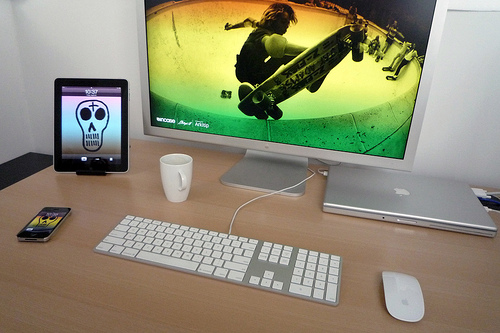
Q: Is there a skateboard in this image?
A: Yes, there is a skateboard.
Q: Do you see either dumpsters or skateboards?
A: Yes, there is a skateboard.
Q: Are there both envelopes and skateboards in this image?
A: No, there is a skateboard but no envelopes.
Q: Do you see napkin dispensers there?
A: No, there are no napkin dispensers.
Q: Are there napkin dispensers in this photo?
A: No, there are no napkin dispensers.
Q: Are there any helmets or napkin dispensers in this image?
A: No, there are no napkin dispensers or helmets.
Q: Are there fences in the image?
A: No, there are no fences.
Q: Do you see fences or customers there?
A: No, there are no fences or customers.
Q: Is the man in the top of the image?
A: Yes, the man is in the top of the image.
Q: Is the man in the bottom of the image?
A: No, the man is in the top of the image.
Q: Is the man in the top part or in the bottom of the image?
A: The man is in the top of the image.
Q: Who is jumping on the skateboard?
A: The man is jumping on the skateboard.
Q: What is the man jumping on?
A: The man is jumping on the skateboard.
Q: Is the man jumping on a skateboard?
A: Yes, the man is jumping on a skateboard.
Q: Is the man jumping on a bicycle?
A: No, the man is jumping on a skateboard.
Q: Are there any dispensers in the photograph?
A: No, there are no dispensers.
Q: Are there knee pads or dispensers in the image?
A: No, there are no dispensers or knee pads.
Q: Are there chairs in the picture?
A: No, there are no chairs.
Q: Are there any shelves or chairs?
A: No, there are no chairs or shelves.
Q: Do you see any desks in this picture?
A: Yes, there is a desk.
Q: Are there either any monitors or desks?
A: Yes, there is a desk.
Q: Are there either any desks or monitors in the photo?
A: Yes, there is a desk.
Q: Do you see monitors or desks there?
A: Yes, there is a desk.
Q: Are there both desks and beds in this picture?
A: No, there is a desk but no beds.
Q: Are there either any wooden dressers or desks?
A: Yes, there is a wood desk.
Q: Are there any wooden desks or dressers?
A: Yes, there is a wood desk.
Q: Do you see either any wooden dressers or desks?
A: Yes, there is a wood desk.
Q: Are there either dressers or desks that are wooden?
A: Yes, the desk is wooden.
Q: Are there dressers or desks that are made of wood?
A: Yes, the desk is made of wood.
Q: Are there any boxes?
A: No, there are no boxes.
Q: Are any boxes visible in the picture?
A: No, there are no boxes.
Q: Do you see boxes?
A: No, there are no boxes.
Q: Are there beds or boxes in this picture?
A: No, there are no boxes or beds.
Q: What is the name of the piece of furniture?
A: The piece of furniture is a desk.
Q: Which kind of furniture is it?
A: The piece of furniture is a desk.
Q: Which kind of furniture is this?
A: This is a desk.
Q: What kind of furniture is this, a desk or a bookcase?
A: This is a desk.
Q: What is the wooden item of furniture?
A: The piece of furniture is a desk.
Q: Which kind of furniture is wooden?
A: The furniture is a desk.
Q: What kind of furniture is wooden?
A: The furniture is a desk.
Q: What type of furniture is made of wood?
A: The furniture is a desk.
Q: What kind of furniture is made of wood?
A: The furniture is a desk.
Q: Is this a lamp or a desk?
A: This is a desk.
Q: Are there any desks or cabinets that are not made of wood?
A: No, there is a desk but it is made of wood.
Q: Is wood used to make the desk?
A: Yes, the desk is made of wood.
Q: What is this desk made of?
A: The desk is made of wood.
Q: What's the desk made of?
A: The desk is made of wood.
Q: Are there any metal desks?
A: No, there is a desk but it is made of wood.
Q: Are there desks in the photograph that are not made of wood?
A: No, there is a desk but it is made of wood.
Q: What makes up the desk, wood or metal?
A: The desk is made of wood.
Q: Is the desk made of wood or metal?
A: The desk is made of wood.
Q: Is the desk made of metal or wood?
A: The desk is made of wood.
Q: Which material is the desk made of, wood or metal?
A: The desk is made of wood.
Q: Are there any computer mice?
A: Yes, there is a computer mouse.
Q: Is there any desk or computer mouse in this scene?
A: Yes, there is a computer mouse.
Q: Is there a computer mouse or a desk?
A: Yes, there is a computer mouse.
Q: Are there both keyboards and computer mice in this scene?
A: Yes, there are both a computer mouse and a keyboard.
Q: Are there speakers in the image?
A: No, there are no speakers.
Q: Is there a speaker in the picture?
A: No, there are no speakers.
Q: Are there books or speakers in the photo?
A: No, there are no speakers or books.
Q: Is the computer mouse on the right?
A: Yes, the computer mouse is on the right of the image.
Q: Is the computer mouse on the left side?
A: No, the computer mouse is on the right of the image.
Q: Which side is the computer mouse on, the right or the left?
A: The computer mouse is on the right of the image.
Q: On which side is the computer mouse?
A: The computer mouse is on the right of the image.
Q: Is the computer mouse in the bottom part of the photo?
A: Yes, the computer mouse is in the bottom of the image.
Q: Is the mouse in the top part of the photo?
A: No, the mouse is in the bottom of the image.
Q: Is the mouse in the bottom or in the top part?
A: The mouse is in the bottom of the image.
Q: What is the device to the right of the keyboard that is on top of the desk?
A: The device is a computer mouse.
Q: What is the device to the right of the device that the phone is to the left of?
A: The device is a computer mouse.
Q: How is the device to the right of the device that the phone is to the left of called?
A: The device is a computer mouse.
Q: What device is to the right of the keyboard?
A: The device is a computer mouse.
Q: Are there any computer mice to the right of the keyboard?
A: Yes, there is a computer mouse to the right of the keyboard.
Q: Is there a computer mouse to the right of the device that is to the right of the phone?
A: Yes, there is a computer mouse to the right of the keyboard.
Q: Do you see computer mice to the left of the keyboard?
A: No, the computer mouse is to the right of the keyboard.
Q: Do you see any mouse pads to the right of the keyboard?
A: No, there is a computer mouse to the right of the keyboard.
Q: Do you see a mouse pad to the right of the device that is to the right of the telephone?
A: No, there is a computer mouse to the right of the keyboard.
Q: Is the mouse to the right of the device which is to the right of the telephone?
A: Yes, the mouse is to the right of the keyboard.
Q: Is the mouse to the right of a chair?
A: No, the mouse is to the right of the keyboard.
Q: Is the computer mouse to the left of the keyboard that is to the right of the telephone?
A: No, the computer mouse is to the right of the keyboard.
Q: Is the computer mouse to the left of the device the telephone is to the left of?
A: No, the computer mouse is to the right of the keyboard.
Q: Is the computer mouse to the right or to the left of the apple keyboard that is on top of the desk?
A: The computer mouse is to the right of the keyboard.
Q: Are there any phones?
A: Yes, there is a phone.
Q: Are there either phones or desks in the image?
A: Yes, there is a phone.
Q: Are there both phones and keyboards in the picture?
A: Yes, there are both a phone and a keyboard.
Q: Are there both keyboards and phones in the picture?
A: Yes, there are both a phone and a keyboard.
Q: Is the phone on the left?
A: Yes, the phone is on the left of the image.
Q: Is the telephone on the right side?
A: No, the telephone is on the left of the image.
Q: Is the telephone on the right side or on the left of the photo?
A: The telephone is on the left of the image.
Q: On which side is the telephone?
A: The telephone is on the left of the image.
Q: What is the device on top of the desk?
A: The device is a phone.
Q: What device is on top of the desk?
A: The device is a phone.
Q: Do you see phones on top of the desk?
A: Yes, there is a phone on top of the desk.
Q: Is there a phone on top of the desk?
A: Yes, there is a phone on top of the desk.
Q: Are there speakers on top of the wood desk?
A: No, there is a phone on top of the desk.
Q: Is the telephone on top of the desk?
A: Yes, the telephone is on top of the desk.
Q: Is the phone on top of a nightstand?
A: No, the phone is on top of the desk.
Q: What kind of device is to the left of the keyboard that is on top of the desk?
A: The device is a phone.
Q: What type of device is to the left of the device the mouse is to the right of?
A: The device is a phone.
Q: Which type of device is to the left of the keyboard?
A: The device is a phone.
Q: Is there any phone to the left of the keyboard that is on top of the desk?
A: Yes, there is a phone to the left of the keyboard.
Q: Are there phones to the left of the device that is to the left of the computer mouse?
A: Yes, there is a phone to the left of the keyboard.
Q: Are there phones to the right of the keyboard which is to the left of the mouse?
A: No, the phone is to the left of the keyboard.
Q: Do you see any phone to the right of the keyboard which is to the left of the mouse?
A: No, the phone is to the left of the keyboard.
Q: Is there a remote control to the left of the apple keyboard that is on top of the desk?
A: No, there is a phone to the left of the keyboard.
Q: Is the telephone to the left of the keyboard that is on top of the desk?
A: Yes, the telephone is to the left of the keyboard.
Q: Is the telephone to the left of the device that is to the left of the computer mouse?
A: Yes, the telephone is to the left of the keyboard.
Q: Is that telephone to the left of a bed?
A: No, the telephone is to the left of the keyboard.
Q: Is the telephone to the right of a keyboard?
A: No, the telephone is to the left of a keyboard.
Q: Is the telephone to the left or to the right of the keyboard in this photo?
A: The telephone is to the left of the keyboard.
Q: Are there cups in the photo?
A: Yes, there is a cup.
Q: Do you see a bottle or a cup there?
A: Yes, there is a cup.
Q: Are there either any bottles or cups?
A: Yes, there is a cup.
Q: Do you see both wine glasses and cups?
A: No, there is a cup but no wine glasses.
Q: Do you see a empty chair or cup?
A: Yes, there is an empty cup.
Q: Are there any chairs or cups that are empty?
A: Yes, the cup is empty.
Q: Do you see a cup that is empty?
A: Yes, there is an empty cup.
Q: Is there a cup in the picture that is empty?
A: Yes, there is a cup that is empty.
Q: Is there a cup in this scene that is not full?
A: Yes, there is a empty cup.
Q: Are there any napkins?
A: No, there are no napkins.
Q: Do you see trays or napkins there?
A: No, there are no napkins or trays.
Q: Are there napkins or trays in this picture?
A: No, there are no napkins or trays.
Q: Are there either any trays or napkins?
A: No, there are no napkins or trays.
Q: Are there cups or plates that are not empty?
A: No, there is a cup but it is empty.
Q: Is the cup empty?
A: Yes, the cup is empty.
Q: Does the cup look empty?
A: Yes, the cup is empty.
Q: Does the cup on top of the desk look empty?
A: Yes, the cup is empty.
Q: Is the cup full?
A: No, the cup is empty.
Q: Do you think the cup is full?
A: No, the cup is empty.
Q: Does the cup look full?
A: No, the cup is empty.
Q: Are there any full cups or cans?
A: No, there is a cup but it is empty.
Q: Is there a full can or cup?
A: No, there is a cup but it is empty.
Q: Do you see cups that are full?
A: No, there is a cup but it is empty.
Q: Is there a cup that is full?
A: No, there is a cup but it is empty.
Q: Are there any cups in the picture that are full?
A: No, there is a cup but it is empty.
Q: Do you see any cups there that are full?
A: No, there is a cup but it is empty.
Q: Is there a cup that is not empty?
A: No, there is a cup but it is empty.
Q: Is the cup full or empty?
A: The cup is empty.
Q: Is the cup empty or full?
A: The cup is empty.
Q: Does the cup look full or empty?
A: The cup is empty.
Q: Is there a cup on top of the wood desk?
A: Yes, there is a cup on top of the desk.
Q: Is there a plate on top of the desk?
A: No, there is a cup on top of the desk.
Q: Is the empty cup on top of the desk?
A: Yes, the cup is on top of the desk.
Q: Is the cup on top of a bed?
A: No, the cup is on top of the desk.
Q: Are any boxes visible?
A: No, there are no boxes.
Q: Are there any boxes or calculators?
A: No, there are no boxes or calculators.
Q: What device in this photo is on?
A: The device is a monitor.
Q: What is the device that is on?
A: The device is a monitor.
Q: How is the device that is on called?
A: The device is a monitor.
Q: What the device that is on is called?
A: The device is a monitor.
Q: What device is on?
A: The device is a monitor.